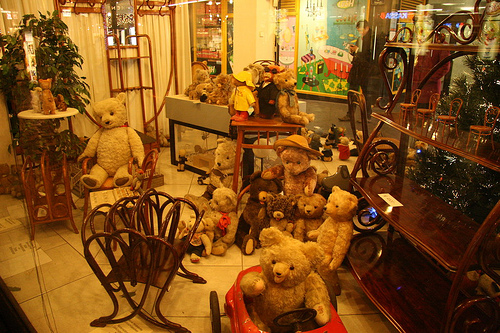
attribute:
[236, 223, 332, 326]
stuffed bear — toy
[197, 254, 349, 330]
car — red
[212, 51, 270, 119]
bear — stuffed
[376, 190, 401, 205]
paper — small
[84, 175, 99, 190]
paw — teddy bear's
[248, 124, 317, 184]
bear — stuffed, brown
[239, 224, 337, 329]
teddy bear — brown, sitting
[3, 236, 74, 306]
tile — beige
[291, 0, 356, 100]
painting — colorful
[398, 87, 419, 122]
chairs — miniature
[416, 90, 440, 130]
chairs — miniature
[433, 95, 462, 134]
chairs — miniature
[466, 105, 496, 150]
chairs — miniature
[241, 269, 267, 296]
bear paw — raised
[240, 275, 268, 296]
paw — teddy bear's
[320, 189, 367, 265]
teddy bear — brown, stuffed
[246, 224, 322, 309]
teddy bear — stuffed, brown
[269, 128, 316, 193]
teddy bear — stuffed, brown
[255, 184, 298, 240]
teddy bear — stuffed, brown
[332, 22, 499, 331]
shelf — brown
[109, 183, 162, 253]
rack — brown, wicker rack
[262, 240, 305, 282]
face — bear's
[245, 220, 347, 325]
bear — stuffed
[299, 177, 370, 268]
bear — stuffed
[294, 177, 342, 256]
bear — stuffed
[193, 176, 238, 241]
bear — stuffed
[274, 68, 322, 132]
bear — stuffed